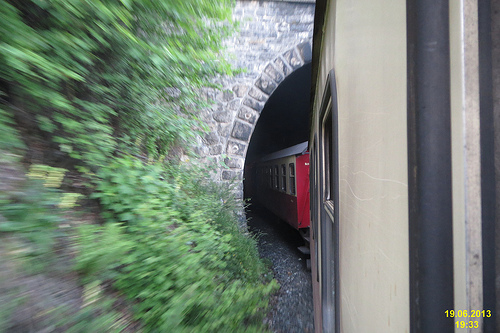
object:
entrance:
[236, 57, 314, 297]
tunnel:
[224, 34, 317, 294]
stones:
[251, 73, 277, 97]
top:
[267, 141, 308, 161]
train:
[243, 0, 499, 332]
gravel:
[258, 240, 311, 333]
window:
[321, 99, 334, 215]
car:
[308, 0, 500, 333]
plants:
[0, 0, 284, 333]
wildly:
[1, 0, 279, 332]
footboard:
[296, 245, 309, 255]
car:
[266, 137, 309, 229]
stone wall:
[179, 0, 317, 232]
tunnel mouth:
[241, 40, 354, 293]